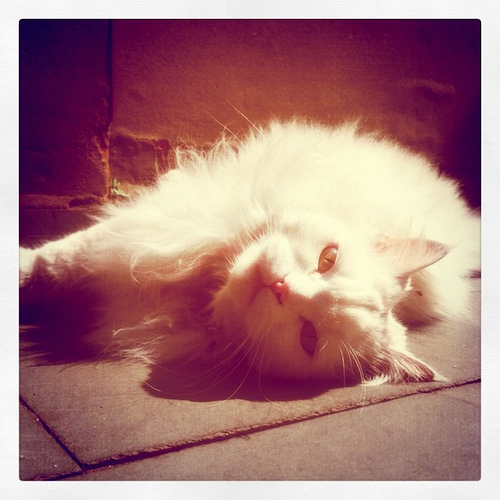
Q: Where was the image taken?
A: It was taken at the pavement.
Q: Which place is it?
A: It is a pavement.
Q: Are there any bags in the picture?
A: No, there are no bags.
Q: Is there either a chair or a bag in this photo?
A: No, there are no bags or chairs.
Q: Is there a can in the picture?
A: No, there are no cans.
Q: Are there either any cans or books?
A: No, there are no cans or books.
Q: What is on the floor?
A: The rug is on the floor.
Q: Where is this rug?
A: The rug is on the floor.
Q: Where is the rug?
A: The rug is on the floor.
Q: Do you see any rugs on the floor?
A: Yes, there is a rug on the floor.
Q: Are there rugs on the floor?
A: Yes, there is a rug on the floor.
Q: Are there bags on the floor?
A: No, there is a rug on the floor.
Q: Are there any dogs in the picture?
A: No, there are no dogs.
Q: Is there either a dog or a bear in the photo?
A: No, there are no dogs or bears.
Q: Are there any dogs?
A: No, there are no dogs.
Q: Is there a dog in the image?
A: No, there are no dogs.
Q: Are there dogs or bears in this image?
A: No, there are no dogs or bears.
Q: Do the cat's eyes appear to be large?
A: Yes, the eyes are large.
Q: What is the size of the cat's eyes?
A: The eyes are large.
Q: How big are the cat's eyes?
A: The eyes are large.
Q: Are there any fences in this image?
A: No, there are no fences.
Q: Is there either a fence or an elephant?
A: No, there are no fences or elephants.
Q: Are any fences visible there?
A: No, there are no fences.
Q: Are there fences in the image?
A: No, there are no fences.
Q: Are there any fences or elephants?
A: No, there are no fences or elephants.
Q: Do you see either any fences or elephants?
A: No, there are no fences or elephants.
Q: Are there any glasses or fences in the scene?
A: No, there are no fences or glasses.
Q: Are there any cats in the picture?
A: Yes, there is a cat.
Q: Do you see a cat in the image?
A: Yes, there is a cat.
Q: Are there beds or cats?
A: Yes, there is a cat.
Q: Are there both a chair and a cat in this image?
A: No, there is a cat but no chairs.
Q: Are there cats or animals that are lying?
A: Yes, the cat is lying.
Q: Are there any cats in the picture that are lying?
A: Yes, there is a cat that is lying.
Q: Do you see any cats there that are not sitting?
A: Yes, there is a cat that is lying .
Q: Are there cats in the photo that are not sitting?
A: Yes, there is a cat that is lying.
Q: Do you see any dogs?
A: No, there are no dogs.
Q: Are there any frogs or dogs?
A: No, there are no dogs or frogs.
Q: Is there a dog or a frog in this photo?
A: No, there are no dogs or frogs.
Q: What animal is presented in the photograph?
A: The animal is a cat.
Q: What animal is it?
A: The animal is a cat.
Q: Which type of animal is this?
A: That is a cat.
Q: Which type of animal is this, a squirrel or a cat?
A: That is a cat.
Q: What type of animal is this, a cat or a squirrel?
A: That is a cat.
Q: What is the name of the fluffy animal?
A: The animal is a cat.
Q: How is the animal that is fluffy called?
A: The animal is a cat.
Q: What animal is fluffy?
A: The animal is a cat.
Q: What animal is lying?
A: The animal is a cat.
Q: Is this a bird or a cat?
A: This is a cat.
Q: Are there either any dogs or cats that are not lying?
A: No, there is a cat but it is lying.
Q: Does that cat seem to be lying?
A: Yes, the cat is lying.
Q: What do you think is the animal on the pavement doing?
A: The cat is lying.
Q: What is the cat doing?
A: The cat is lying.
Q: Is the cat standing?
A: No, the cat is lying.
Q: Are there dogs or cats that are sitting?
A: No, there is a cat but it is lying.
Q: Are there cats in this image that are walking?
A: No, there is a cat but it is lying.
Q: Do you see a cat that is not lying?
A: No, there is a cat but it is lying.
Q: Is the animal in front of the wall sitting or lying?
A: The cat is lying.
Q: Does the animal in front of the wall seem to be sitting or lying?
A: The cat is lying.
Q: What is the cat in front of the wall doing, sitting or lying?
A: The cat is lying.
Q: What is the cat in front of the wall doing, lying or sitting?
A: The cat is lying.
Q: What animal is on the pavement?
A: The cat is on the pavement.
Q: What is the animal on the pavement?
A: The animal is a cat.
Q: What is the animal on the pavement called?
A: The animal is a cat.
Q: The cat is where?
A: The cat is on the pavement.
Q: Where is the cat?
A: The cat is on the pavement.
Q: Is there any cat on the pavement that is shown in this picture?
A: Yes, there is a cat on the pavement.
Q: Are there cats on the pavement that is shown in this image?
A: Yes, there is a cat on the pavement.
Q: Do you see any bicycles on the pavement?
A: No, there is a cat on the pavement.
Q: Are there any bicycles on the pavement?
A: No, there is a cat on the pavement.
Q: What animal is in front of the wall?
A: The cat is in front of the wall.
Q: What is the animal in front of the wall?
A: The animal is a cat.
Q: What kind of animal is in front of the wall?
A: The animal is a cat.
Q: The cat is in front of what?
A: The cat is in front of the wall.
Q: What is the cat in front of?
A: The cat is in front of the wall.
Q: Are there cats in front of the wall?
A: Yes, there is a cat in front of the wall.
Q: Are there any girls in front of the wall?
A: No, there is a cat in front of the wall.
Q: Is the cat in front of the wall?
A: Yes, the cat is in front of the wall.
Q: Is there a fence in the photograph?
A: No, there are no fences.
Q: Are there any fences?
A: No, there are no fences.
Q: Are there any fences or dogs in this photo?
A: No, there are no fences or dogs.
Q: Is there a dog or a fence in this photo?
A: No, there are no fences or dogs.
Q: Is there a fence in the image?
A: No, there are no fences.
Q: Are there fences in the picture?
A: No, there are no fences.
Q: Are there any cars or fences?
A: No, there are no fences or cars.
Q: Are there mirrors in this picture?
A: No, there are no mirrors.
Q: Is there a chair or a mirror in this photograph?
A: No, there are no mirrors or chairs.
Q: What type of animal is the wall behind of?
A: The wall is behind the cat.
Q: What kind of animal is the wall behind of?
A: The wall is behind the cat.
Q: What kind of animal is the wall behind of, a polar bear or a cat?
A: The wall is behind a cat.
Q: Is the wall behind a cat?
A: Yes, the wall is behind a cat.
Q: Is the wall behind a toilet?
A: No, the wall is behind a cat.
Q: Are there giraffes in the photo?
A: No, there are no giraffes.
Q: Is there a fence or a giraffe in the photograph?
A: No, there are no giraffes or fences.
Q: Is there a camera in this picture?
A: Yes, there is a camera.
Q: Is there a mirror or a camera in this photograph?
A: Yes, there is a camera.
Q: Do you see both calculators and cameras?
A: No, there is a camera but no calculators.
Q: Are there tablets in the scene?
A: No, there are no tablets.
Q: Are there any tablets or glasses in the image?
A: No, there are no tablets or glasses.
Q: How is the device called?
A: The device is a camera.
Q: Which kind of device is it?
A: The device is a camera.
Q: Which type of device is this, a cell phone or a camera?
A: That is a camera.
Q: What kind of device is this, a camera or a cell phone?
A: That is a camera.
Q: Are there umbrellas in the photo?
A: No, there are no umbrellas.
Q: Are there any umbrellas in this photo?
A: No, there are no umbrellas.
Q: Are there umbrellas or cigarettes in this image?
A: No, there are no umbrellas or cigarettes.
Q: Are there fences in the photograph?
A: No, there are no fences.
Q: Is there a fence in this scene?
A: No, there are no fences.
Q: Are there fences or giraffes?
A: No, there are no fences or giraffes.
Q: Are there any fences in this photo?
A: No, there are no fences.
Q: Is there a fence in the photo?
A: No, there are no fences.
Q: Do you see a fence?
A: No, there are no fences.